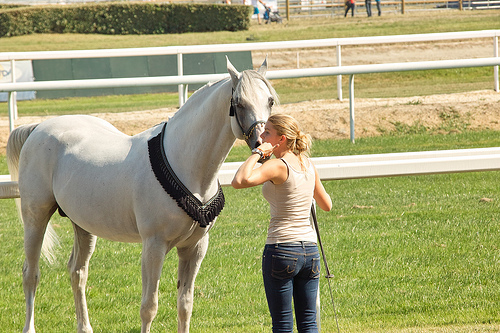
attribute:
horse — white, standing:
[6, 52, 278, 331]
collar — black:
[142, 117, 239, 232]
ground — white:
[367, 157, 401, 199]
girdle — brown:
[146, 118, 227, 228]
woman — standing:
[236, 118, 339, 330]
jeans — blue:
[256, 245, 330, 325]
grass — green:
[364, 227, 466, 282]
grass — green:
[1, 167, 499, 331]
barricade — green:
[27, 46, 259, 99]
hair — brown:
[266, 112, 313, 161]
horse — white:
[8, 52, 290, 314]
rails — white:
[230, 24, 395, 162]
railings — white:
[2, 32, 498, 144]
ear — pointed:
[262, 58, 268, 74]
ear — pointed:
[224, 52, 242, 87]